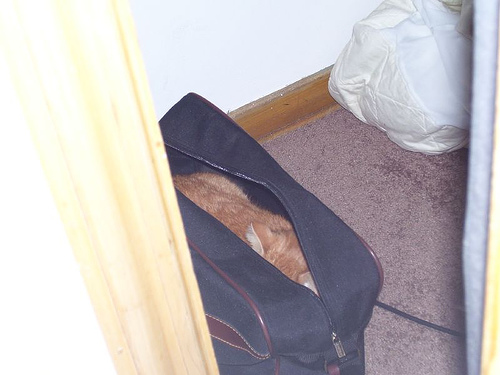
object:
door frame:
[0, 0, 498, 372]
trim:
[0, 1, 220, 374]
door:
[109, 0, 476, 372]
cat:
[165, 169, 324, 299]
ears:
[249, 218, 274, 259]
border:
[225, 66, 344, 150]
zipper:
[328, 329, 348, 359]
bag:
[154, 89, 390, 373]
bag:
[324, 0, 473, 157]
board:
[223, 66, 339, 120]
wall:
[125, 0, 390, 142]